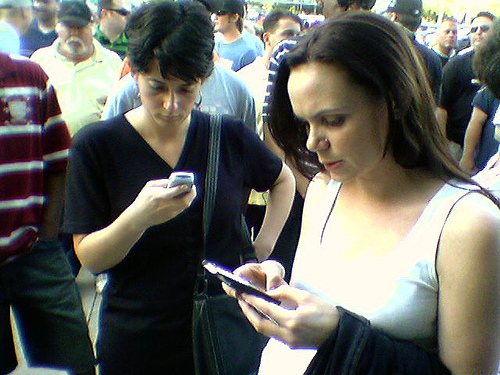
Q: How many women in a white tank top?
A: One.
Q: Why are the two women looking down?
A: Looking at phones.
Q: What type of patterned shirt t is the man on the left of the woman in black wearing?
A: Striped.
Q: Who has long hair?
A: Woman in white tank.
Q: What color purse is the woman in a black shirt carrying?
A: Black.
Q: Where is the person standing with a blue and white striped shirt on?
A: Behind the woman in the white tank.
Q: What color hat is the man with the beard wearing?
A: Black.